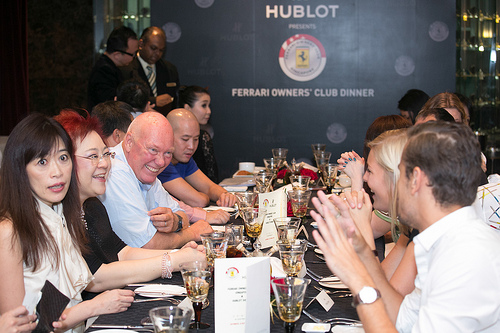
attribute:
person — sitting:
[1, 110, 136, 331]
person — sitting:
[51, 103, 211, 294]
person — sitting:
[96, 108, 215, 251]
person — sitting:
[88, 96, 230, 224]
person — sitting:
[160, 106, 240, 209]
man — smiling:
[97, 108, 214, 251]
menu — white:
[223, 257, 267, 331]